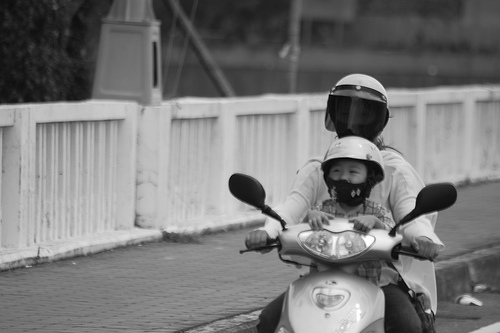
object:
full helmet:
[324, 72, 391, 138]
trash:
[454, 293, 483, 306]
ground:
[0, 176, 494, 332]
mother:
[245, 72, 439, 332]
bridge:
[0, 83, 499, 333]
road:
[410, 242, 499, 333]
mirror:
[226, 171, 270, 206]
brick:
[470, 215, 500, 229]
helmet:
[319, 136, 387, 204]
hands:
[346, 214, 379, 234]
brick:
[37, 264, 64, 278]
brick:
[198, 287, 217, 293]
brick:
[199, 312, 221, 320]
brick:
[238, 293, 263, 302]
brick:
[153, 325, 178, 331]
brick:
[159, 300, 181, 308]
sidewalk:
[0, 180, 500, 331]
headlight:
[295, 226, 375, 261]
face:
[326, 157, 371, 187]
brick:
[184, 265, 193, 270]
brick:
[209, 280, 236, 296]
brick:
[132, 284, 143, 302]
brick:
[160, 312, 188, 322]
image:
[0, 0, 499, 333]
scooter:
[226, 172, 458, 333]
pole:
[90, 0, 166, 103]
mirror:
[413, 182, 468, 213]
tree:
[0, 1, 91, 102]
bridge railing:
[0, 84, 499, 270]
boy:
[302, 134, 397, 287]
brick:
[16, 277, 30, 285]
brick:
[82, 303, 96, 317]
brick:
[138, 290, 148, 300]